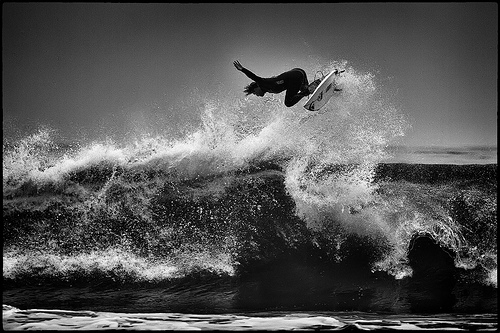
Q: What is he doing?
A: Surfing.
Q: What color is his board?
A: White.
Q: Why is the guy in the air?
A: He made a jump.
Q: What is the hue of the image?
A: Black and white.